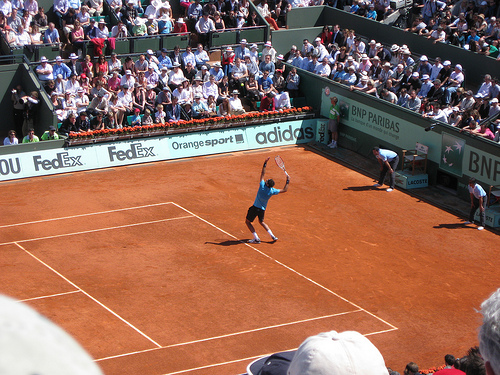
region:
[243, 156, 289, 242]
male tennis player in blue shirt and dark shorts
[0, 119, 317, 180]
advertising set up on sideline stands at tennis match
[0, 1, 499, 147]
spectators in stands at tennis match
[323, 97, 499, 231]
tennis match staff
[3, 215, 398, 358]
singles match tennis court lines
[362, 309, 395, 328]
alley base line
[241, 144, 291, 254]
tennis player serving ball behind baseline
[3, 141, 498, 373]
clay tennis court and out of bounds area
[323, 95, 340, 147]
tennis match staff person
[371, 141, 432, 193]
tennis match linesman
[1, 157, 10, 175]
black letter on wall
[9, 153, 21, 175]
black letter on wall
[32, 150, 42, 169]
black letter on wall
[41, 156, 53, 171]
black letter on wall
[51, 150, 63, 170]
black letter on wall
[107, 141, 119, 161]
black letter on wall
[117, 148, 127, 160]
black letter on wall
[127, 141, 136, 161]
black letter on wall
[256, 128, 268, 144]
black letter on wall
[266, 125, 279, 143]
black letter on wall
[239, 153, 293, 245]
Tennis player serving ball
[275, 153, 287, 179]
Tennis racket in man's hand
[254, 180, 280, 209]
Light blue shirt on man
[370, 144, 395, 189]
Man bent over on court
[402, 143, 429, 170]
Chair behind man on court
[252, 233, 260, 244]
White sock on tennis player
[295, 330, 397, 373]
White cap on spectator's head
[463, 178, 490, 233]
Man with hands on thighs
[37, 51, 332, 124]
Spectators watching the tennis match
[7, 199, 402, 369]
White lines on tennis court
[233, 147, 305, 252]
a man holding a tennis racket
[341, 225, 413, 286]
red surface of the tennis court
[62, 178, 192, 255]
white lines painted on the court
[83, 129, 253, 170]
black lettering on the green wall of the court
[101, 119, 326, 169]
sponsor logos on the wall of the court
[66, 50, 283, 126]
many spectators in the stands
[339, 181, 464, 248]
shadows of the referree's cast on the tennis court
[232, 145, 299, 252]
a man serving a tennis ball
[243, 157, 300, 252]
a man wearing a blue shirt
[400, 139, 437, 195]
an empty chair on the edge of the tennis court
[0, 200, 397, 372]
White lines mark the tennis court.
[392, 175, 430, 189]
The name and logo of Lacoste on a wooden box.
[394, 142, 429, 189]
A chair on top of a box.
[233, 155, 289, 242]
A tennis player about to hit the ball.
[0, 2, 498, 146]
The stands are full of people.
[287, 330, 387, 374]
The top of a hat.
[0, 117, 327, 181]
The names of sponsors are written on the wall.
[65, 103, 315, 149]
A display of red flowers.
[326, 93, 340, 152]
A man standing against the wall.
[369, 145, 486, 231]
Two judges watching the match.